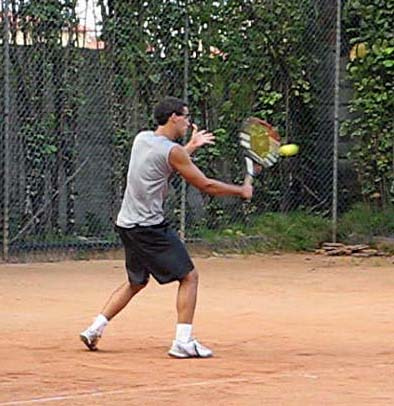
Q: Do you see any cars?
A: No, there are no cars.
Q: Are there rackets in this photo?
A: Yes, there is a racket.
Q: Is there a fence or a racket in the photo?
A: Yes, there is a racket.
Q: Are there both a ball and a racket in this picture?
A: Yes, there are both a racket and a ball.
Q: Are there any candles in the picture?
A: No, there are no candles.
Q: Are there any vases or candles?
A: No, there are no candles or vases.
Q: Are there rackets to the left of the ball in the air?
A: Yes, there is a racket to the left of the ball.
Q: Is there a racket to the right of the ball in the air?
A: No, the racket is to the left of the ball.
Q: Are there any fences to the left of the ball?
A: No, there is a racket to the left of the ball.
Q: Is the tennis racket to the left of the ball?
A: Yes, the tennis racket is to the left of the ball.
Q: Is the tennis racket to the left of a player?
A: No, the tennis racket is to the left of the ball.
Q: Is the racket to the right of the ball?
A: No, the racket is to the left of the ball.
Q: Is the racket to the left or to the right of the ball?
A: The racket is to the left of the ball.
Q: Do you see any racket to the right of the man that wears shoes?
A: Yes, there is a racket to the right of the man.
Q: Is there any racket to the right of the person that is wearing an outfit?
A: Yes, there is a racket to the right of the man.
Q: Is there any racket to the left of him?
A: No, the racket is to the right of the man.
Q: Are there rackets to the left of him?
A: No, the racket is to the right of the man.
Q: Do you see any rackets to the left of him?
A: No, the racket is to the right of the man.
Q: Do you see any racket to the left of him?
A: No, the racket is to the right of the man.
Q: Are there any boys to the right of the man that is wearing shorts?
A: No, there is a racket to the right of the man.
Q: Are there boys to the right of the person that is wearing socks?
A: No, there is a racket to the right of the man.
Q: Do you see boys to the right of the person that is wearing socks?
A: No, there is a racket to the right of the man.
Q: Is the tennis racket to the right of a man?
A: Yes, the tennis racket is to the right of a man.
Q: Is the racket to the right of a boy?
A: No, the racket is to the right of a man.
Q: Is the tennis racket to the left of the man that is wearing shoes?
A: No, the tennis racket is to the right of the man.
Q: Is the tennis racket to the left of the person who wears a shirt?
A: No, the tennis racket is to the right of the man.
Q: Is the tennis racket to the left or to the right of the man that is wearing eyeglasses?
A: The tennis racket is to the right of the man.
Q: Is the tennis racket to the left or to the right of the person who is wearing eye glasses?
A: The tennis racket is to the right of the man.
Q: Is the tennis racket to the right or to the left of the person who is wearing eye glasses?
A: The tennis racket is to the right of the man.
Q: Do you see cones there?
A: No, there are no cones.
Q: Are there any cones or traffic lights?
A: No, there are no cones or traffic lights.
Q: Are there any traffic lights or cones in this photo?
A: No, there are no cones or traffic lights.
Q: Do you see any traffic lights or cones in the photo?
A: No, there are no cones or traffic lights.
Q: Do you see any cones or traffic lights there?
A: No, there are no cones or traffic lights.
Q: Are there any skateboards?
A: No, there are no skateboards.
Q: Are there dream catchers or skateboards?
A: No, there are no skateboards or dream catchers.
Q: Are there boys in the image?
A: No, there are no boys.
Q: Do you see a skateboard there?
A: No, there are no skateboards.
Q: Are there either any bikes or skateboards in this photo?
A: No, there are no skateboards or bikes.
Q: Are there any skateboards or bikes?
A: No, there are no skateboards or bikes.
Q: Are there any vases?
A: No, there are no vases.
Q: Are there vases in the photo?
A: No, there are no vases.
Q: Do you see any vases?
A: No, there are no vases.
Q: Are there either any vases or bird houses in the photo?
A: No, there are no vases or bird houses.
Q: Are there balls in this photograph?
A: Yes, there is a ball.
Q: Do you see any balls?
A: Yes, there is a ball.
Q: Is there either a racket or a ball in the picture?
A: Yes, there is a ball.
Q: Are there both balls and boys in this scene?
A: No, there is a ball but no boys.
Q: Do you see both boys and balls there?
A: No, there is a ball but no boys.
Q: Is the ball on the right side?
A: Yes, the ball is on the right of the image.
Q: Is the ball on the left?
A: No, the ball is on the right of the image.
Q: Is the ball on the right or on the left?
A: The ball is on the right of the image.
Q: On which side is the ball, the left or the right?
A: The ball is on the right of the image.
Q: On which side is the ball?
A: The ball is on the right of the image.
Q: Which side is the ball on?
A: The ball is on the right of the image.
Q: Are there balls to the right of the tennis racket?
A: Yes, there is a ball to the right of the tennis racket.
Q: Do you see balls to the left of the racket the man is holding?
A: No, the ball is to the right of the racket.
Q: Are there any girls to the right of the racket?
A: No, there is a ball to the right of the racket.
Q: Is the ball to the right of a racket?
A: Yes, the ball is to the right of a racket.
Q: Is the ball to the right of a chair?
A: No, the ball is to the right of a racket.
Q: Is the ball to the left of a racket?
A: No, the ball is to the right of a racket.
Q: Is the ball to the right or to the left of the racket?
A: The ball is to the right of the racket.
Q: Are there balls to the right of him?
A: Yes, there is a ball to the right of the man.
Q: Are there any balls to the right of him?
A: Yes, there is a ball to the right of the man.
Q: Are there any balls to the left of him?
A: No, the ball is to the right of the man.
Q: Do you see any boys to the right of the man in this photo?
A: No, there is a ball to the right of the man.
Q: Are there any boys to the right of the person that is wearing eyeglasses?
A: No, there is a ball to the right of the man.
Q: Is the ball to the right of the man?
A: Yes, the ball is to the right of the man.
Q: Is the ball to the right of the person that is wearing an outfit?
A: Yes, the ball is to the right of the man.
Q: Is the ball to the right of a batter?
A: No, the ball is to the right of the man.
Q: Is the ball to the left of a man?
A: No, the ball is to the right of a man.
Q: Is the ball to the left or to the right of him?
A: The ball is to the right of the man.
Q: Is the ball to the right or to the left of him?
A: The ball is to the right of the man.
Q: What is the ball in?
A: The ball is in the air.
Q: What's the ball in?
A: The ball is in the air.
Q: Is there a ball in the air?
A: Yes, there is a ball in the air.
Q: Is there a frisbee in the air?
A: No, there is a ball in the air.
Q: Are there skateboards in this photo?
A: No, there are no skateboards.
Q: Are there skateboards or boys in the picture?
A: No, there are no skateboards or boys.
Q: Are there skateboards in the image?
A: No, there are no skateboards.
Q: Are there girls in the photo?
A: No, there are no girls.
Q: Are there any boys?
A: No, there are no boys.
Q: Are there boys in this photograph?
A: No, there are no boys.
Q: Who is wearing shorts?
A: The man is wearing shorts.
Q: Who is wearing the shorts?
A: The man is wearing shorts.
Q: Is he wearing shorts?
A: Yes, the man is wearing shorts.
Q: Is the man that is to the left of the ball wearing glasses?
A: No, the man is wearing shorts.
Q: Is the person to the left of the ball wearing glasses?
A: No, the man is wearing shorts.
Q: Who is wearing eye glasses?
A: The man is wearing eye glasses.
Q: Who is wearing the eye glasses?
A: The man is wearing eye glasses.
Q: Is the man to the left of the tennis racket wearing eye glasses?
A: Yes, the man is wearing eye glasses.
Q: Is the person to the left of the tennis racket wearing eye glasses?
A: Yes, the man is wearing eye glasses.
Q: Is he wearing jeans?
A: No, the man is wearing eye glasses.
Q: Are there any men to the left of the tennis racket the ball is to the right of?
A: Yes, there is a man to the left of the racket.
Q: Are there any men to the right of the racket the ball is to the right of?
A: No, the man is to the left of the racket.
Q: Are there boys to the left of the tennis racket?
A: No, there is a man to the left of the tennis racket.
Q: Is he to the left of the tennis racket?
A: Yes, the man is to the left of the tennis racket.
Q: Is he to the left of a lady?
A: No, the man is to the left of the tennis racket.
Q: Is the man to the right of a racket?
A: No, the man is to the left of a racket.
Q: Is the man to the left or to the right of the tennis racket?
A: The man is to the left of the tennis racket.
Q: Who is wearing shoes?
A: The man is wearing shoes.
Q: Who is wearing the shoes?
A: The man is wearing shoes.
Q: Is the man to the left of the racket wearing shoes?
A: Yes, the man is wearing shoes.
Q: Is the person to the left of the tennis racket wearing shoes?
A: Yes, the man is wearing shoes.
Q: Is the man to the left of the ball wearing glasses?
A: No, the man is wearing shoes.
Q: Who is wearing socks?
A: The man is wearing socks.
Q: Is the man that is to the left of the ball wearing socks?
A: Yes, the man is wearing socks.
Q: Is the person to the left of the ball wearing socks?
A: Yes, the man is wearing socks.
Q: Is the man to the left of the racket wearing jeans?
A: No, the man is wearing socks.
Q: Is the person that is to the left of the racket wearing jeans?
A: No, the man is wearing socks.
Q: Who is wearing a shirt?
A: The man is wearing a shirt.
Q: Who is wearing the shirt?
A: The man is wearing a shirt.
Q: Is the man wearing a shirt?
A: Yes, the man is wearing a shirt.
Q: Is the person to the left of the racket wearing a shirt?
A: Yes, the man is wearing a shirt.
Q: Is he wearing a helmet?
A: No, the man is wearing a shirt.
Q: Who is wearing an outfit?
A: The man is wearing an outfit.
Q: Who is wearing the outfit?
A: The man is wearing an outfit.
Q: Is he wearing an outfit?
A: Yes, the man is wearing an outfit.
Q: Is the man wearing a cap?
A: No, the man is wearing an outfit.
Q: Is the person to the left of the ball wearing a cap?
A: No, the man is wearing an outfit.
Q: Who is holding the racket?
A: The man is holding the racket.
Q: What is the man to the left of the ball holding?
A: The man is holding the tennis racket.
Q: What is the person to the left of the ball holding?
A: The man is holding the tennis racket.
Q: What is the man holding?
A: The man is holding the tennis racket.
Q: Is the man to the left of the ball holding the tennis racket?
A: Yes, the man is holding the tennis racket.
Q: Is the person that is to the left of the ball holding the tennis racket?
A: Yes, the man is holding the tennis racket.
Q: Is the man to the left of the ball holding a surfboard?
A: No, the man is holding the tennis racket.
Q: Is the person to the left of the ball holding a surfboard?
A: No, the man is holding the tennis racket.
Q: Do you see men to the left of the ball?
A: Yes, there is a man to the left of the ball.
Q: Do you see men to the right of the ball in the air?
A: No, the man is to the left of the ball.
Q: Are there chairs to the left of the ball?
A: No, there is a man to the left of the ball.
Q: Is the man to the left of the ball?
A: Yes, the man is to the left of the ball.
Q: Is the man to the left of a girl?
A: No, the man is to the left of the ball.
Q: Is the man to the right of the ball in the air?
A: No, the man is to the left of the ball.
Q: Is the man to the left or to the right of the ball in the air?
A: The man is to the left of the ball.